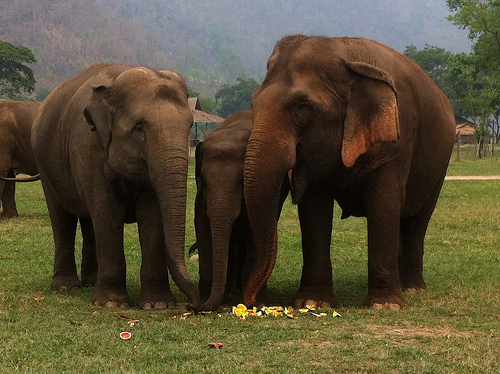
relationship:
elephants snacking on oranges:
[28, 44, 445, 273] [227, 296, 342, 321]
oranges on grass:
[227, 296, 342, 321] [0, 133, 500, 374]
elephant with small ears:
[29, 56, 213, 312] [78, 80, 122, 148]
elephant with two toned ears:
[227, 21, 435, 314] [342, 58, 403, 170]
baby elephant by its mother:
[195, 106, 265, 315] [227, 21, 435, 314]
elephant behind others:
[3, 94, 57, 221] [29, 56, 213, 312]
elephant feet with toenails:
[290, 282, 340, 314] [290, 295, 334, 311]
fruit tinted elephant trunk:
[229, 299, 252, 320] [240, 136, 278, 305]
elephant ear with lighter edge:
[342, 58, 403, 170] [345, 113, 396, 168]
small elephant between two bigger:
[195, 106, 265, 315] [63, 50, 383, 188]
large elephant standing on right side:
[227, 21, 435, 314] [273, 40, 490, 356]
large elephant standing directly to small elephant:
[227, 21, 435, 314] [195, 106, 265, 315]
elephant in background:
[29, 56, 213, 312] [3, 98, 52, 168]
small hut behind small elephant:
[181, 89, 227, 149] [195, 106, 265, 315]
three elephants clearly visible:
[28, 44, 445, 273] [133, 14, 238, 69]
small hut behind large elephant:
[181, 89, 227, 149] [227, 21, 464, 316]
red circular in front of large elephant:
[205, 334, 226, 353] [227, 21, 464, 316]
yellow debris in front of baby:
[225, 293, 290, 319] [187, 112, 299, 312]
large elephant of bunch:
[227, 21, 464, 316] [28, 44, 445, 273]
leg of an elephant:
[86, 199, 134, 311] [29, 56, 213, 312]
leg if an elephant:
[86, 199, 134, 311] [29, 56, 213, 312]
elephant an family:
[29, 56, 213, 312] [28, 44, 445, 273]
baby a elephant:
[195, 106, 265, 315] [29, 56, 213, 312]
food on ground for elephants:
[227, 296, 342, 321] [28, 44, 445, 273]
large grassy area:
[455, 174, 496, 248] [340, 296, 476, 331]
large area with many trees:
[4, 8, 492, 222] [419, 7, 499, 97]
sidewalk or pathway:
[445, 171, 500, 184] [445, 171, 492, 184]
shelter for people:
[448, 109, 491, 163] [453, 101, 495, 151]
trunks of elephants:
[143, 169, 285, 310] [28, 44, 445, 273]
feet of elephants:
[75, 284, 408, 315] [28, 44, 445, 273]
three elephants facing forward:
[28, 44, 445, 273] [62, 69, 390, 212]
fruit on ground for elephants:
[227, 296, 342, 321] [28, 44, 445, 273]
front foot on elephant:
[290, 282, 340, 314] [227, 21, 435, 314]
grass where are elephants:
[53, 312, 175, 371] [28, 44, 445, 273]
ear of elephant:
[78, 80, 122, 148] [29, 56, 213, 312]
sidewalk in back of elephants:
[445, 171, 492, 184] [28, 44, 445, 273]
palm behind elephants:
[205, 71, 256, 112] [28, 44, 445, 273]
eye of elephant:
[130, 122, 150, 138] [29, 56, 213, 312]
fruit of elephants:
[159, 290, 343, 334] [28, 44, 445, 273]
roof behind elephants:
[188, 92, 218, 130] [28, 44, 445, 273]